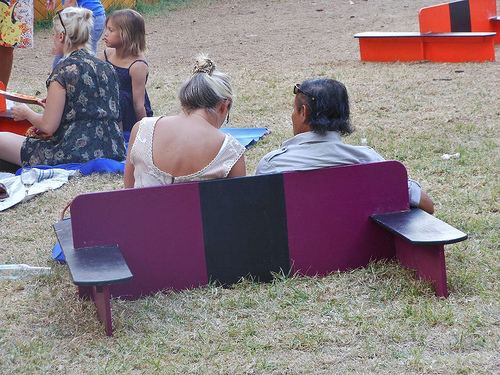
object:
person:
[3, 7, 125, 165]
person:
[118, 57, 245, 185]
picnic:
[14, 20, 494, 374]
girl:
[97, 5, 154, 137]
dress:
[110, 53, 156, 123]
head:
[291, 78, 353, 135]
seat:
[47, 159, 469, 340]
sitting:
[134, 131, 434, 227]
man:
[253, 78, 435, 215]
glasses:
[292, 81, 316, 101]